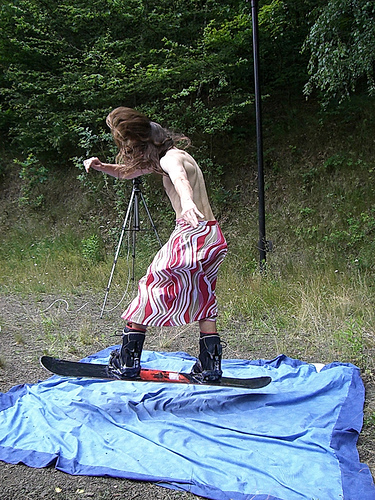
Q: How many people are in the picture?
A: One.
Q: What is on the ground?
A: Blanket.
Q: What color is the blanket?
A: Blue.